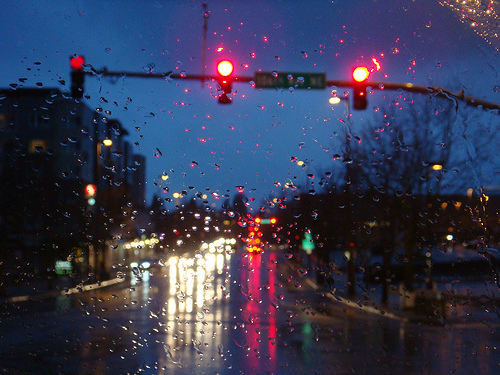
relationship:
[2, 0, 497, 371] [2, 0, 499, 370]
raindrops on glass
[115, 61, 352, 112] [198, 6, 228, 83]
pole on traffic camera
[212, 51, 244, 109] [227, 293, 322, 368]
light on road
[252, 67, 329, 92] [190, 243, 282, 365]
sign on road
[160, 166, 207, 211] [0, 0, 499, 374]
rain drop on wind shield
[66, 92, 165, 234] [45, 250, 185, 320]
building on street